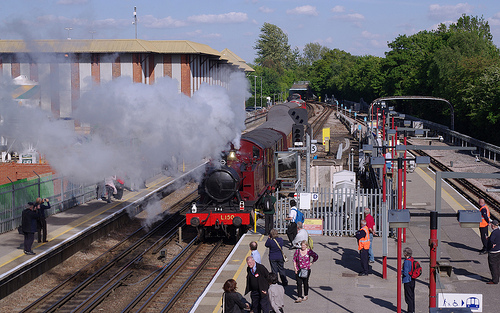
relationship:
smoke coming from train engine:
[4, 69, 251, 186] [181, 129, 287, 235]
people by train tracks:
[213, 187, 317, 311] [35, 188, 224, 312]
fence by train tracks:
[275, 186, 388, 235] [35, 188, 224, 312]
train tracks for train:
[35, 188, 224, 312] [186, 83, 311, 244]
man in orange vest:
[354, 221, 378, 275] [353, 225, 371, 250]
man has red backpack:
[401, 246, 426, 312] [407, 258, 423, 279]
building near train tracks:
[4, 36, 248, 151] [35, 188, 224, 312]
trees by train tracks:
[311, 51, 390, 112] [35, 188, 224, 312]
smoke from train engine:
[4, 69, 251, 186] [181, 129, 287, 235]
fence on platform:
[275, 186, 388, 235] [195, 139, 497, 312]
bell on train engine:
[225, 151, 239, 163] [181, 129, 287, 235]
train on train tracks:
[186, 83, 311, 244] [35, 188, 224, 312]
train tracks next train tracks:
[31, 188, 227, 312] [35, 188, 224, 312]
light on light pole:
[383, 208, 410, 236] [426, 231, 446, 312]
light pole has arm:
[426, 231, 446, 312] [413, 206, 457, 220]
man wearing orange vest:
[354, 221, 378, 275] [353, 225, 371, 250]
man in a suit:
[239, 256, 273, 312] [246, 268, 272, 308]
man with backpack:
[401, 246, 426, 312] [407, 258, 423, 279]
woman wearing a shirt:
[267, 225, 291, 286] [265, 237, 288, 261]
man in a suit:
[21, 199, 42, 253] [21, 209, 38, 254]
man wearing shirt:
[239, 256, 273, 312] [248, 266, 259, 274]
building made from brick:
[4, 36, 248, 151] [180, 58, 188, 87]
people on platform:
[213, 187, 317, 311] [195, 139, 497, 312]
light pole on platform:
[426, 231, 446, 312] [195, 139, 497, 312]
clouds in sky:
[139, 10, 251, 38] [5, 4, 499, 69]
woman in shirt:
[267, 225, 291, 286] [265, 237, 288, 261]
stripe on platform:
[183, 232, 246, 312] [195, 139, 497, 312]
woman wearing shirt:
[267, 225, 291, 286] [265, 237, 288, 261]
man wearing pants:
[401, 246, 426, 312] [406, 280, 417, 312]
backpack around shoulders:
[407, 258, 423, 279] [403, 259, 420, 263]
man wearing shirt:
[401, 246, 426, 312] [399, 256, 412, 288]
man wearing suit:
[239, 256, 273, 312] [246, 268, 272, 308]